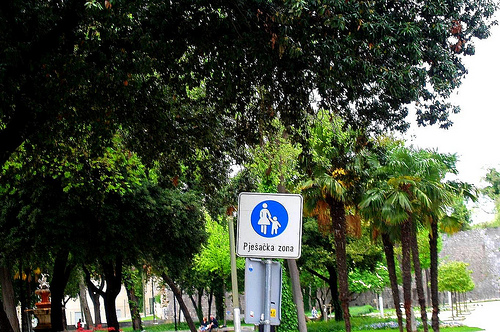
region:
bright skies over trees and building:
[379, 5, 497, 327]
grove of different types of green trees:
[16, 123, 496, 330]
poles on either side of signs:
[217, 181, 310, 328]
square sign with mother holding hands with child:
[233, 185, 304, 259]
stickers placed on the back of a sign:
[235, 255, 286, 329]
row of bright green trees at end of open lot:
[433, 252, 497, 328]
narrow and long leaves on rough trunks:
[356, 134, 468, 330]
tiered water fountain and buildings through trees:
[5, 268, 242, 328]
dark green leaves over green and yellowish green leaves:
[198, 3, 483, 185]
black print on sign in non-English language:
[235, 191, 304, 258]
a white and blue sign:
[231, 187, 317, 255]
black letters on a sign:
[237, 237, 314, 260]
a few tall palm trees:
[223, 135, 480, 330]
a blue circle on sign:
[250, 194, 308, 239]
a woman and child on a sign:
[253, 200, 296, 245]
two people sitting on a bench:
[180, 309, 245, 330]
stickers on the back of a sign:
[242, 261, 281, 331]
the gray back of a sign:
[234, 256, 289, 331]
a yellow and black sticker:
[263, 298, 278, 321]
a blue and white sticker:
[245, 259, 259, 274]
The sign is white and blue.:
[236, 190, 303, 263]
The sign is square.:
[235, 188, 303, 260]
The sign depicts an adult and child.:
[233, 188, 305, 262]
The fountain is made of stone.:
[21, 263, 61, 329]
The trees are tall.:
[0, 0, 499, 329]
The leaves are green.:
[0, 1, 498, 282]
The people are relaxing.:
[194, 312, 221, 330]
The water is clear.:
[353, 288, 495, 328]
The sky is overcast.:
[226, 0, 498, 225]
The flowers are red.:
[71, 315, 118, 330]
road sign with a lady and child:
[233, 187, 304, 259]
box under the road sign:
[245, 250, 281, 330]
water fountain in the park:
[24, 265, 69, 330]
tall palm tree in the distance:
[367, 153, 430, 330]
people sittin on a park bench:
[194, 313, 216, 330]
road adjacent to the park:
[379, 281, 496, 324]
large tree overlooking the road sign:
[0, 2, 497, 324]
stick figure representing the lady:
[254, 201, 273, 236]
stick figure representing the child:
[267, 214, 284, 236]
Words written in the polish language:
[236, 238, 296, 253]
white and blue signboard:
[239, 191, 298, 259]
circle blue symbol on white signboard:
[251, 199, 287, 239]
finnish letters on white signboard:
[240, 240, 296, 259]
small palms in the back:
[89, 120, 462, 330]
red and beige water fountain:
[26, 286, 73, 327]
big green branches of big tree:
[3, 9, 493, 164]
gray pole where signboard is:
[262, 258, 276, 330]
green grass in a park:
[12, 297, 455, 330]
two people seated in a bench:
[202, 314, 218, 330]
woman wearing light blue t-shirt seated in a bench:
[311, 307, 318, 320]